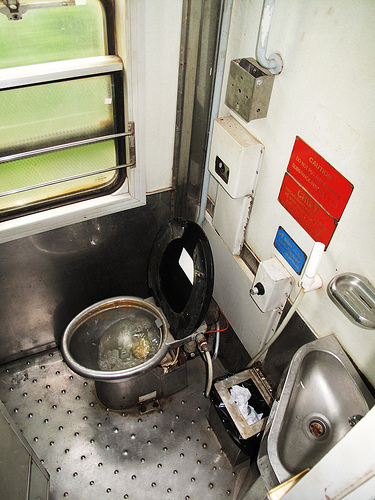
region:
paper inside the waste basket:
[231, 362, 266, 435]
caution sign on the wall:
[289, 141, 348, 216]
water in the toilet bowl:
[92, 317, 158, 362]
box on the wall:
[222, 50, 274, 123]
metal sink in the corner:
[259, 339, 368, 477]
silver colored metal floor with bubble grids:
[0, 345, 251, 497]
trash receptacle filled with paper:
[201, 362, 273, 467]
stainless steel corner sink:
[255, 330, 373, 483]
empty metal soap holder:
[324, 270, 371, 330]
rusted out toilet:
[57, 292, 169, 377]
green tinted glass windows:
[0, 0, 127, 221]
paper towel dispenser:
[205, 113, 262, 196]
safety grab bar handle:
[254, 0, 283, 74]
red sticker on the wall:
[286, 135, 355, 221]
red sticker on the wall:
[276, 174, 337, 252]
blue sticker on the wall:
[271, 225, 306, 276]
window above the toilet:
[0, 1, 145, 243]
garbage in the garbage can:
[208, 361, 276, 469]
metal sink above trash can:
[255, 333, 373, 491]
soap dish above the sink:
[325, 272, 373, 330]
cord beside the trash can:
[245, 287, 303, 368]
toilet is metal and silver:
[57, 295, 206, 412]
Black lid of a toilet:
[144, 200, 217, 349]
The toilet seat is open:
[136, 210, 215, 348]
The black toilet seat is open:
[138, 211, 224, 349]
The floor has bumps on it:
[105, 423, 180, 485]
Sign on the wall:
[286, 128, 358, 218]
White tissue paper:
[235, 381, 253, 422]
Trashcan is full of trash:
[211, 358, 278, 490]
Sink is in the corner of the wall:
[240, 322, 358, 497]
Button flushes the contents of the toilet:
[247, 255, 299, 333]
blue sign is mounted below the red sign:
[263, 219, 319, 283]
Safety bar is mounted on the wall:
[233, 7, 306, 82]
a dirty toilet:
[36, 240, 222, 381]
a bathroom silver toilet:
[81, 299, 216, 420]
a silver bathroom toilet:
[80, 312, 170, 431]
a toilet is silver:
[73, 287, 194, 436]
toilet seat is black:
[144, 215, 211, 340]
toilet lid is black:
[157, 218, 214, 334]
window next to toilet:
[1, 72, 120, 215]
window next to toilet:
[1, 3, 108, 66]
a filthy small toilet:
[30, 191, 227, 422]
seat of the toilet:
[140, 220, 215, 329]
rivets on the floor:
[6, 335, 224, 498]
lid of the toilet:
[149, 212, 222, 332]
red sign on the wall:
[272, 139, 360, 250]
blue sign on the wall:
[267, 224, 323, 281]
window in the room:
[5, 3, 140, 239]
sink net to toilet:
[262, 340, 362, 476]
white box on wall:
[243, 248, 288, 317]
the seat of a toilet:
[145, 210, 205, 340]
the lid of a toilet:
[152, 208, 215, 324]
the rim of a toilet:
[47, 311, 96, 354]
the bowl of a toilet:
[64, 313, 166, 392]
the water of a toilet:
[100, 323, 153, 365]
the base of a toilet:
[105, 372, 185, 407]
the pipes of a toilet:
[169, 344, 233, 406]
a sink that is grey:
[270, 338, 373, 478]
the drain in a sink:
[298, 415, 334, 447]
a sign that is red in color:
[272, 132, 353, 241]